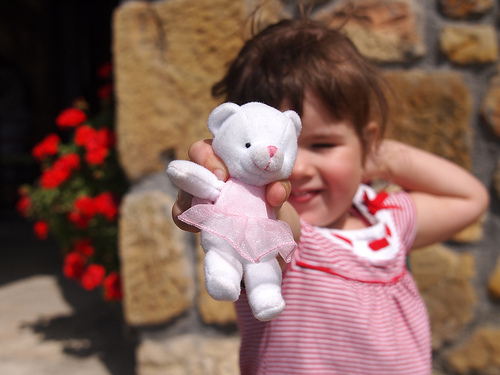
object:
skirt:
[175, 180, 296, 264]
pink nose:
[267, 145, 277, 158]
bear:
[167, 102, 305, 321]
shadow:
[18, 308, 135, 373]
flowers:
[15, 107, 125, 301]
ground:
[0, 239, 135, 373]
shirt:
[234, 190, 431, 375]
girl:
[168, 9, 493, 371]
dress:
[228, 179, 460, 374]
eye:
[244, 140, 251, 150]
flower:
[58, 100, 107, 165]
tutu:
[175, 172, 298, 263]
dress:
[234, 185, 430, 374]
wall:
[116, 47, 500, 349]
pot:
[51, 251, 122, 339]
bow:
[355, 184, 403, 216]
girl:
[172, 8, 489, 364]